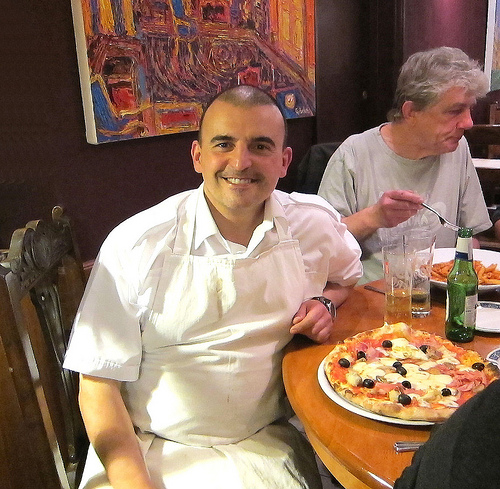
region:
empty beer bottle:
[441, 220, 476, 342]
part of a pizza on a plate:
[314, 323, 460, 428]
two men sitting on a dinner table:
[68, 54, 498, 487]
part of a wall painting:
[66, 1, 336, 81]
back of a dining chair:
[3, 202, 76, 487]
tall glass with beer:
[378, 229, 415, 323]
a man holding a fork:
[343, 33, 499, 240]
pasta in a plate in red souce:
[476, 225, 498, 295]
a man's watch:
[311, 284, 341, 322]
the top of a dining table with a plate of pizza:
[274, 351, 414, 458]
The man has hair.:
[369, 44, 495, 180]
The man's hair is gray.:
[380, 33, 495, 169]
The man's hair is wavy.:
[381, 32, 493, 175]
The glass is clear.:
[399, 230, 437, 321]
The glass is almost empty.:
[401, 224, 440, 320]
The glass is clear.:
[375, 228, 417, 336]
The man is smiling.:
[168, 70, 301, 227]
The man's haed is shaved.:
[181, 81, 308, 232]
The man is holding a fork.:
[318, 37, 498, 245]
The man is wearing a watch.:
[58, 77, 369, 348]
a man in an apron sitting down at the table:
[64, 80, 366, 487]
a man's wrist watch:
[313, 292, 343, 319]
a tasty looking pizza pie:
[323, 320, 495, 426]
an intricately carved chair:
[0, 201, 87, 483]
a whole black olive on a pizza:
[360, 375, 370, 390]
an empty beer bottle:
[441, 225, 478, 345]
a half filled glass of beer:
[383, 240, 414, 332]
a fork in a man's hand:
[419, 186, 464, 233]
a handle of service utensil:
[394, 437, 420, 454]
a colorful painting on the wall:
[71, 0, 320, 145]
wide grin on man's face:
[212, 170, 272, 192]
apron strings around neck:
[145, 186, 250, 292]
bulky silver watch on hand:
[302, 290, 349, 320]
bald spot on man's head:
[227, 77, 270, 110]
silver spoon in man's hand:
[418, 197, 468, 238]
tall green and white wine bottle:
[442, 221, 491, 333]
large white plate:
[313, 313, 482, 419]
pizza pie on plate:
[332, 327, 479, 406]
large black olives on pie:
[341, 355, 426, 401]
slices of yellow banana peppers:
[448, 349, 475, 364]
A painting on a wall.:
[69, 5, 316, 143]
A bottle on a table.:
[445, 226, 479, 343]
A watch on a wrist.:
[312, 291, 337, 318]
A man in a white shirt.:
[64, 85, 360, 486]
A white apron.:
[71, 194, 316, 486]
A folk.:
[416, 197, 469, 233]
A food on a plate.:
[318, 320, 498, 429]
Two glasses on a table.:
[379, 227, 434, 327]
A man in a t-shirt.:
[316, 80, 493, 282]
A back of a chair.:
[0, 205, 103, 485]